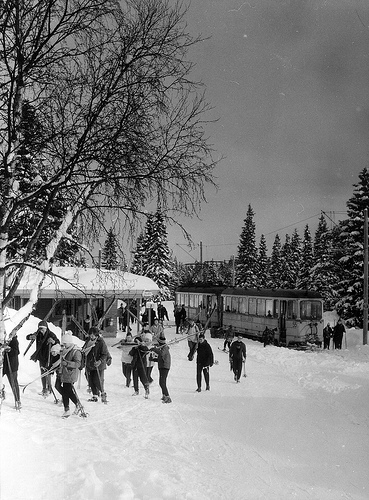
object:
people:
[228, 334, 247, 384]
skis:
[91, 354, 106, 403]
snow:
[0, 299, 369, 500]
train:
[172, 284, 326, 352]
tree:
[0, 0, 227, 377]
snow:
[0, 0, 220, 358]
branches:
[0, 156, 113, 373]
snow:
[95, 165, 369, 329]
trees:
[333, 167, 369, 333]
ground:
[0, 297, 369, 500]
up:
[0, 297, 258, 414]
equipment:
[0, 299, 251, 423]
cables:
[173, 201, 362, 250]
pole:
[196, 240, 204, 286]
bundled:
[0, 216, 349, 264]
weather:
[0, 0, 369, 500]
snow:
[5, 263, 163, 296]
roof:
[0, 266, 160, 301]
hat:
[62, 329, 74, 345]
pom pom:
[64, 325, 74, 337]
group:
[0, 302, 248, 420]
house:
[0, 258, 159, 348]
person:
[330, 319, 347, 353]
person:
[321, 321, 329, 350]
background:
[0, 0, 369, 499]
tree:
[234, 199, 259, 286]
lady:
[54, 328, 84, 420]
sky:
[0, 0, 369, 276]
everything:
[0, 0, 369, 500]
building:
[0, 259, 159, 346]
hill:
[0, 293, 369, 500]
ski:
[0, 294, 369, 467]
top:
[0, 264, 162, 302]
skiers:
[229, 332, 248, 380]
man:
[186, 332, 213, 393]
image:
[0, 0, 369, 500]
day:
[0, 0, 369, 500]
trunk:
[0, 175, 96, 368]